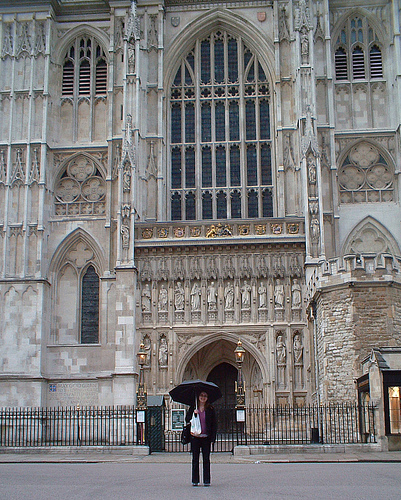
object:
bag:
[181, 421, 191, 445]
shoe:
[202, 480, 212, 488]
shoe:
[188, 479, 198, 487]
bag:
[189, 410, 202, 435]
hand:
[192, 405, 200, 417]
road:
[0, 461, 400, 498]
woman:
[183, 386, 218, 486]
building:
[0, 0, 399, 441]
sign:
[235, 406, 247, 422]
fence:
[158, 404, 376, 443]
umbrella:
[168, 378, 220, 422]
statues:
[288, 279, 303, 311]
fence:
[1, 407, 144, 446]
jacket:
[184, 402, 218, 441]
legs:
[190, 440, 201, 484]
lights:
[233, 335, 243, 367]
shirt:
[197, 406, 207, 434]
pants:
[191, 438, 211, 486]